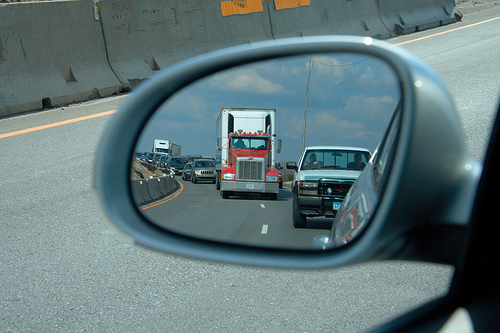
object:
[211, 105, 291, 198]
semi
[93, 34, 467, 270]
mirror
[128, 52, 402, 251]
reflection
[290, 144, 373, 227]
car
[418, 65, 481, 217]
side of car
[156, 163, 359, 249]
road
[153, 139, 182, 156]
truck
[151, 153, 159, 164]
car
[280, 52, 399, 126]
sky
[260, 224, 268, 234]
stripes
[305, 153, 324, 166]
man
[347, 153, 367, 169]
man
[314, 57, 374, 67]
electrical wire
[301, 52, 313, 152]
pole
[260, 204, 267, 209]
line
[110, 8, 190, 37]
graffiti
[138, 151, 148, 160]
car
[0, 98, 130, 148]
line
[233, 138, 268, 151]
front window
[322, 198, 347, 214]
radiator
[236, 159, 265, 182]
grill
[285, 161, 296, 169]
mirror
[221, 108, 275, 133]
smoke stack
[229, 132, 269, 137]
pipe